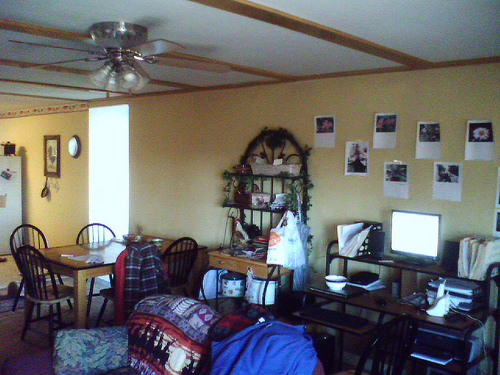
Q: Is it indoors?
A: Yes, it is indoors.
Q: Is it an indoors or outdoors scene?
A: It is indoors.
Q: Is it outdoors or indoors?
A: It is indoors.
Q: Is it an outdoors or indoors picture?
A: It is indoors.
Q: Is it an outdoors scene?
A: No, it is indoors.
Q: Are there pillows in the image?
A: No, there are no pillows.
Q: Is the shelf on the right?
A: Yes, the shelf is on the right of the image.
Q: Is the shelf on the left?
A: No, the shelf is on the right of the image.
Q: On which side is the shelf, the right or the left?
A: The shelf is on the right of the image.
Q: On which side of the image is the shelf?
A: The shelf is on the right of the image.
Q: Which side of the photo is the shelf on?
A: The shelf is on the right of the image.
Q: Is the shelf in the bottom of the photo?
A: Yes, the shelf is in the bottom of the image.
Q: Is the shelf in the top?
A: No, the shelf is in the bottom of the image.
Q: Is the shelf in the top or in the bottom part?
A: The shelf is in the bottom of the image.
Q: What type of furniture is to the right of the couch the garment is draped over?
A: The piece of furniture is a shelf.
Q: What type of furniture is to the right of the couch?
A: The piece of furniture is a shelf.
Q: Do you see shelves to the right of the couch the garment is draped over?
A: Yes, there is a shelf to the right of the couch.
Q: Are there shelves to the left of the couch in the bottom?
A: No, the shelf is to the right of the couch.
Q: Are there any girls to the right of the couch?
A: No, there is a shelf to the right of the couch.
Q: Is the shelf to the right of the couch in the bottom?
A: Yes, the shelf is to the right of the couch.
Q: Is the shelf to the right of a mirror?
A: No, the shelf is to the right of the couch.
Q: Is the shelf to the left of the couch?
A: No, the shelf is to the right of the couch.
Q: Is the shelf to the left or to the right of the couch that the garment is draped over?
A: The shelf is to the right of the couch.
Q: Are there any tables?
A: Yes, there is a table.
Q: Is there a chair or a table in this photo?
A: Yes, there is a table.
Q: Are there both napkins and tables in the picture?
A: No, there is a table but no napkins.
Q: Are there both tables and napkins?
A: No, there is a table but no napkins.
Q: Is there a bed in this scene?
A: No, there are no beds.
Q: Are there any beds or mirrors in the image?
A: No, there are no beds or mirrors.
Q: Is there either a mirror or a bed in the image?
A: No, there are no beds or mirrors.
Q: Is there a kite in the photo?
A: No, there are no kites.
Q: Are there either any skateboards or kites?
A: No, there are no kites or skateboards.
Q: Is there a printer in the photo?
A: Yes, there is a printer.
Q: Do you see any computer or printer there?
A: Yes, there is a printer.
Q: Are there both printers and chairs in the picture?
A: Yes, there are both a printer and a chair.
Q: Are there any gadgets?
A: No, there are no gadgets.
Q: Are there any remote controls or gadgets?
A: No, there are no gadgets or remote controls.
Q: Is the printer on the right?
A: Yes, the printer is on the right of the image.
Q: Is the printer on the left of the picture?
A: No, the printer is on the right of the image.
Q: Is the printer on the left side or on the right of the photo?
A: The printer is on the right of the image.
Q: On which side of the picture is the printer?
A: The printer is on the right of the image.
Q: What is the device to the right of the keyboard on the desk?
A: The device is a printer.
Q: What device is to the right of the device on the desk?
A: The device is a printer.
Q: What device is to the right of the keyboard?
A: The device is a printer.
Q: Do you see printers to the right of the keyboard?
A: Yes, there is a printer to the right of the keyboard.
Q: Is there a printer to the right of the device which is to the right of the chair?
A: Yes, there is a printer to the right of the keyboard.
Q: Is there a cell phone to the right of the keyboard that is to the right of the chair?
A: No, there is a printer to the right of the keyboard.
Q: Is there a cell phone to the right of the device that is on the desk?
A: No, there is a printer to the right of the keyboard.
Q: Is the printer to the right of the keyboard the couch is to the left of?
A: Yes, the printer is to the right of the keyboard.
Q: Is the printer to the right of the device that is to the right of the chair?
A: Yes, the printer is to the right of the keyboard.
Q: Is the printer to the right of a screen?
A: No, the printer is to the right of the keyboard.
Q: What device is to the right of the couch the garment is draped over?
A: The device is a printer.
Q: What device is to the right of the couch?
A: The device is a printer.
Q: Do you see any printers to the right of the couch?
A: Yes, there is a printer to the right of the couch.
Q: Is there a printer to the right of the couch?
A: Yes, there is a printer to the right of the couch.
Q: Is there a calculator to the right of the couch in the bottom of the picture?
A: No, there is a printer to the right of the couch.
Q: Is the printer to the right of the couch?
A: Yes, the printer is to the right of the couch.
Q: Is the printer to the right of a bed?
A: No, the printer is to the right of the couch.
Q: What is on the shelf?
A: The printer is on the shelf.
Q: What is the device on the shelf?
A: The device is a printer.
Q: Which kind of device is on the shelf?
A: The device is a printer.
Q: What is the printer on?
A: The printer is on the shelf.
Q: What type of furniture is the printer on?
A: The printer is on the shelf.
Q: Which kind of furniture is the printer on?
A: The printer is on the shelf.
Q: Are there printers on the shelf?
A: Yes, there is a printer on the shelf.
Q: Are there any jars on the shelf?
A: No, there is a printer on the shelf.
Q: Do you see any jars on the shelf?
A: No, there is a printer on the shelf.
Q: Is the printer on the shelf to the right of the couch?
A: Yes, the printer is on the shelf.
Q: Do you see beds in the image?
A: No, there are no beds.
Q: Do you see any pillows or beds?
A: No, there are no beds or pillows.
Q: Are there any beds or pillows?
A: No, there are no beds or pillows.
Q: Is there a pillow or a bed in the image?
A: No, there are no beds or pillows.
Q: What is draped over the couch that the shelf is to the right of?
A: The garment is draped over the couch.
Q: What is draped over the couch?
A: The garment is draped over the couch.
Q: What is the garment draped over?
A: The garment is draped over the couch.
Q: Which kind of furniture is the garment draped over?
A: The garment is draped over the couch.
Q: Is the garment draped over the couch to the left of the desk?
A: Yes, the garment is draped over the couch.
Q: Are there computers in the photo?
A: Yes, there is a computer.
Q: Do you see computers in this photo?
A: Yes, there is a computer.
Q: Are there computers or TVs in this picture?
A: Yes, there is a computer.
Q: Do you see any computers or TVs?
A: Yes, there is a computer.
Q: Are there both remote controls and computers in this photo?
A: No, there is a computer but no remote controls.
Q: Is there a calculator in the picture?
A: No, there are no calculators.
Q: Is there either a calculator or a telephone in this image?
A: No, there are no calculators or phones.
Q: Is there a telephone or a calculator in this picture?
A: No, there are no calculators or phones.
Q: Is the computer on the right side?
A: Yes, the computer is on the right of the image.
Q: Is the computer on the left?
A: No, the computer is on the right of the image.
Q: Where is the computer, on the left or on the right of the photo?
A: The computer is on the right of the image.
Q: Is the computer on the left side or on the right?
A: The computer is on the right of the image.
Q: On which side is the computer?
A: The computer is on the right of the image.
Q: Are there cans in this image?
A: No, there are no cans.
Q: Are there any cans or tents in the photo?
A: No, there are no cans or tents.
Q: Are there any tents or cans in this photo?
A: No, there are no cans or tents.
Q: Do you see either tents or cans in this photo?
A: No, there are no cans or tents.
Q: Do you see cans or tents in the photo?
A: No, there are no cans or tents.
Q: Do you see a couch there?
A: Yes, there is a couch.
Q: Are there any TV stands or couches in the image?
A: Yes, there is a couch.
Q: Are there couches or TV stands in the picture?
A: Yes, there is a couch.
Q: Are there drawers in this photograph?
A: No, there are no drawers.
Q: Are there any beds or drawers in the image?
A: No, there are no drawers or beds.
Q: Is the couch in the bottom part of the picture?
A: Yes, the couch is in the bottom of the image.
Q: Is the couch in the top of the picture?
A: No, the couch is in the bottom of the image.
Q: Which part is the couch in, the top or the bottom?
A: The couch is in the bottom of the image.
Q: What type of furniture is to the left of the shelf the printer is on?
A: The piece of furniture is a couch.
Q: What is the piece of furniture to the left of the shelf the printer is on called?
A: The piece of furniture is a couch.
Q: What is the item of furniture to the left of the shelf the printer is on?
A: The piece of furniture is a couch.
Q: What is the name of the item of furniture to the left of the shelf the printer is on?
A: The piece of furniture is a couch.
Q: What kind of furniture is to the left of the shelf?
A: The piece of furniture is a couch.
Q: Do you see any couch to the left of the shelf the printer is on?
A: Yes, there is a couch to the left of the shelf.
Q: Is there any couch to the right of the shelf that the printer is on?
A: No, the couch is to the left of the shelf.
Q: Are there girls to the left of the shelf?
A: No, there is a couch to the left of the shelf.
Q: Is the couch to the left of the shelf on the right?
A: Yes, the couch is to the left of the shelf.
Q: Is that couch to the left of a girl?
A: No, the couch is to the left of the shelf.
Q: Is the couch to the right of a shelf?
A: No, the couch is to the left of a shelf.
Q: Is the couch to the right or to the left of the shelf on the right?
A: The couch is to the left of the shelf.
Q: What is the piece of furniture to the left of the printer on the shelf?
A: The piece of furniture is a couch.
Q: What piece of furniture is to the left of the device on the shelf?
A: The piece of furniture is a couch.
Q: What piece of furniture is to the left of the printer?
A: The piece of furniture is a couch.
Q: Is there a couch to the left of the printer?
A: Yes, there is a couch to the left of the printer.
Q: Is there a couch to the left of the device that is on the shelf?
A: Yes, there is a couch to the left of the printer.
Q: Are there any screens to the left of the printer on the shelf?
A: No, there is a couch to the left of the printer.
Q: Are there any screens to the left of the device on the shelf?
A: No, there is a couch to the left of the printer.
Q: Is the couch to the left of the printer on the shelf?
A: Yes, the couch is to the left of the printer.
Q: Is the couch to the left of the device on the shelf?
A: Yes, the couch is to the left of the printer.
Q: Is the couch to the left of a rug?
A: No, the couch is to the left of the printer.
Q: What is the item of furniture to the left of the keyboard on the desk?
A: The piece of furniture is a couch.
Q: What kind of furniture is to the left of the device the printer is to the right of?
A: The piece of furniture is a couch.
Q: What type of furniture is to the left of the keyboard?
A: The piece of furniture is a couch.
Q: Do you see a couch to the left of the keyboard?
A: Yes, there is a couch to the left of the keyboard.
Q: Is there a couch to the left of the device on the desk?
A: Yes, there is a couch to the left of the keyboard.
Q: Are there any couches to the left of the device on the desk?
A: Yes, there is a couch to the left of the keyboard.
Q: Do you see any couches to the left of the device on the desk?
A: Yes, there is a couch to the left of the keyboard.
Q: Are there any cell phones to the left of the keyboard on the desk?
A: No, there is a couch to the left of the keyboard.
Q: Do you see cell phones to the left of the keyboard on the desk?
A: No, there is a couch to the left of the keyboard.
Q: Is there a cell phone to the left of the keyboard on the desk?
A: No, there is a couch to the left of the keyboard.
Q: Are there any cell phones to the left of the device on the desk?
A: No, there is a couch to the left of the keyboard.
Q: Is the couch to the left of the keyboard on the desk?
A: Yes, the couch is to the left of the keyboard.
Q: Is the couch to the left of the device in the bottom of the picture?
A: Yes, the couch is to the left of the keyboard.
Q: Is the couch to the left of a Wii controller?
A: No, the couch is to the left of the keyboard.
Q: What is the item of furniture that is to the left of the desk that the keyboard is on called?
A: The piece of furniture is a couch.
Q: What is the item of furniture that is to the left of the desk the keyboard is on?
A: The piece of furniture is a couch.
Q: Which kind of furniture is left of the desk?
A: The piece of furniture is a couch.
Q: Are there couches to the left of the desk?
A: Yes, there is a couch to the left of the desk.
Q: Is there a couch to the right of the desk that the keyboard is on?
A: No, the couch is to the left of the desk.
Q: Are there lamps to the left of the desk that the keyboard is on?
A: No, there is a couch to the left of the desk.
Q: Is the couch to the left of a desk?
A: Yes, the couch is to the left of a desk.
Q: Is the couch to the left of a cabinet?
A: No, the couch is to the left of a desk.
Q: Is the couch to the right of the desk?
A: No, the couch is to the left of the desk.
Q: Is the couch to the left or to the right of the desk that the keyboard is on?
A: The couch is to the left of the desk.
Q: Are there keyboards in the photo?
A: Yes, there is a keyboard.